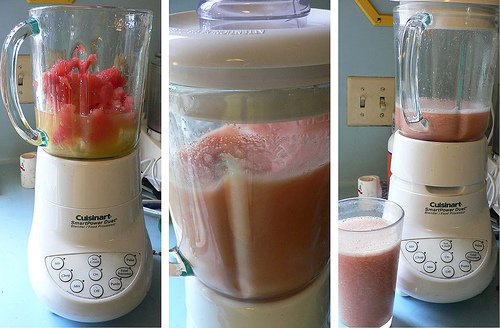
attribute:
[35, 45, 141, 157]
fruit — blending, chunky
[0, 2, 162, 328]
blender — on the left, half full, glass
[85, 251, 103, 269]
button — white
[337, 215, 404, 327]
shake — on the right, blended, pink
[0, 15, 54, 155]
handle — glass, clear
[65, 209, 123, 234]
name — black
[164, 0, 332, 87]
cover — white, clear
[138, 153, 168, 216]
cord — white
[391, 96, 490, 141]
shake — being mixed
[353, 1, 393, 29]
frame — yellow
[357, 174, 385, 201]
mug — white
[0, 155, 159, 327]
counter — shiny